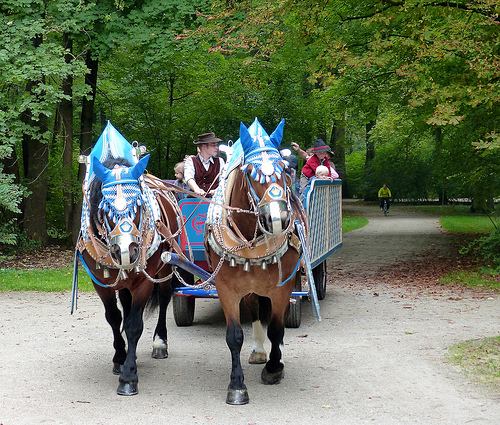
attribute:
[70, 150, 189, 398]
horse — brown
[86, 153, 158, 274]
head — blue, colorful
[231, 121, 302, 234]
head — blue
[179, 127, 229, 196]
man — white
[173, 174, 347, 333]
wagon — beautiful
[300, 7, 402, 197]
tree — lush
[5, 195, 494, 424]
path — dirt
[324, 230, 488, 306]
leaves — red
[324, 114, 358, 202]
trunk — black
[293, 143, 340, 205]
child — looking right, toddler, standing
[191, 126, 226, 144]
hat — brown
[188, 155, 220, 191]
jacket — brown